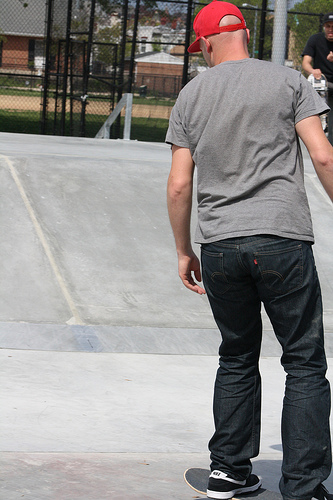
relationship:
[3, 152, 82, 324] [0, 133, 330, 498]
line on concrete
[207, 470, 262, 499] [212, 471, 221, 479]
sneaker has logo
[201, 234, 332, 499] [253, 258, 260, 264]
pants have tag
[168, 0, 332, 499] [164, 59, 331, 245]
man wearing shirt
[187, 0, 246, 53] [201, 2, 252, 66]
hat on head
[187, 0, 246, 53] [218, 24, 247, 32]
hat has fastener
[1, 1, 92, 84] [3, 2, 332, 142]
house across from fence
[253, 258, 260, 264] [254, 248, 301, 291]
tag on pocket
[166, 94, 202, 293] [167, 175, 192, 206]
arm has elbow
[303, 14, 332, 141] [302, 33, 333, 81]
man wearing shirt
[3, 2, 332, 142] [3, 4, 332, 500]
fence at skate park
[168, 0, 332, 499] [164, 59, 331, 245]
man has shirt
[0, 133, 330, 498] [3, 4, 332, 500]
concrete in skate park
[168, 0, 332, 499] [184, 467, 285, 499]
man on skateboard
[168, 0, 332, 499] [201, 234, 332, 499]
man has pants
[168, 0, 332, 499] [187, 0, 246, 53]
man has hat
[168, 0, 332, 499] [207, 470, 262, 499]
man has sneaker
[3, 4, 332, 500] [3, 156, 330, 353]
skate park has ramp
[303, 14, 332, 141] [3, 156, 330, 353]
man on ramp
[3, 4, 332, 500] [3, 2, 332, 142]
skate park has fence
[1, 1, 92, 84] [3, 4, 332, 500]
house behind skate park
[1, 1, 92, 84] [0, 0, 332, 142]
house in background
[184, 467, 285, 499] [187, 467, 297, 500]
skateboard has tape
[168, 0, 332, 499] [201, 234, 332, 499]
man wearing pants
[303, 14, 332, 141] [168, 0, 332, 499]
man watching man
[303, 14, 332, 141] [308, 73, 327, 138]
man holding skateboard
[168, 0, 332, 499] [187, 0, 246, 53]
man wearing hat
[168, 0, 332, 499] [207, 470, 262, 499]
man wearing sneaker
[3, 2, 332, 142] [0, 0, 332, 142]
fence in background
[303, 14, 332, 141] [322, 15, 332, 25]
man wearing hat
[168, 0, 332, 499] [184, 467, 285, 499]
man standing on skateboard